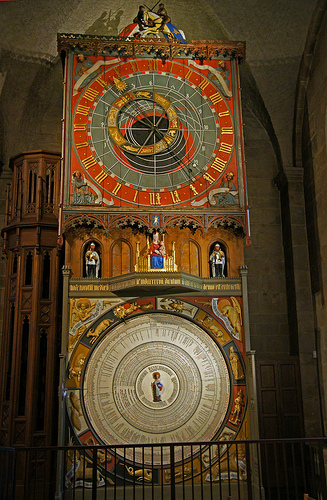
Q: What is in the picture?
A: A little toy tower is in the picture.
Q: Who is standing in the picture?
A: Nobody is standing in the picture.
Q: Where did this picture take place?
A: It took place in a church.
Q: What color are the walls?
A: The walls are grey and brown.